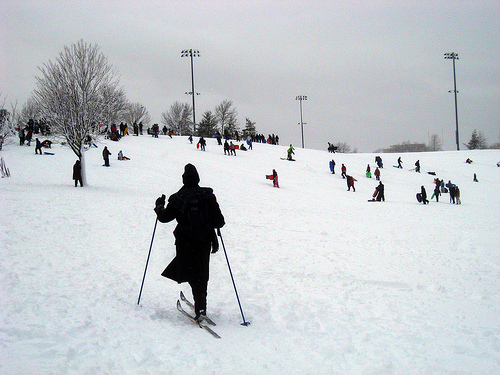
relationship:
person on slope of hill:
[135, 159, 258, 340] [13, 135, 497, 375]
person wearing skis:
[135, 159, 258, 340] [174, 289, 221, 342]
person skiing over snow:
[135, 159, 258, 340] [8, 127, 490, 374]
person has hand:
[135, 159, 258, 340] [153, 194, 169, 208]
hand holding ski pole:
[153, 194, 169, 208] [136, 194, 167, 306]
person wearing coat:
[135, 159, 258, 340] [154, 185, 226, 283]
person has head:
[135, 159, 258, 340] [181, 163, 204, 184]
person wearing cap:
[135, 159, 258, 340] [180, 164, 203, 184]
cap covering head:
[180, 164, 203, 184] [181, 163, 204, 184]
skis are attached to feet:
[174, 289, 221, 342] [196, 308, 210, 327]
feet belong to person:
[196, 308, 210, 327] [135, 159, 258, 340]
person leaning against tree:
[72, 160, 82, 189] [36, 36, 128, 186]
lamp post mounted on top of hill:
[179, 48, 204, 137] [13, 135, 497, 375]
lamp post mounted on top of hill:
[297, 93, 309, 151] [13, 135, 497, 375]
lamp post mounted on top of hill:
[444, 50, 462, 151] [13, 135, 497, 375]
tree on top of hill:
[163, 103, 196, 137] [13, 135, 497, 375]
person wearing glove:
[135, 159, 258, 340] [156, 197, 166, 208]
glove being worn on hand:
[156, 197, 166, 208] [153, 194, 169, 208]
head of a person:
[181, 163, 204, 184] [135, 159, 258, 340]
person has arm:
[135, 159, 258, 340] [155, 192, 177, 224]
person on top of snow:
[135, 159, 258, 340] [8, 127, 490, 374]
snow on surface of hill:
[8, 127, 490, 374] [13, 135, 497, 375]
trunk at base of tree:
[79, 155, 88, 187] [36, 36, 128, 186]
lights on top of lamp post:
[181, 49, 200, 59] [179, 48, 204, 137]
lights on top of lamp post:
[297, 94, 308, 102] [297, 93, 309, 151]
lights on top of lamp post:
[445, 50, 458, 61] [444, 50, 462, 151]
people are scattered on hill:
[105, 119, 479, 202] [13, 135, 497, 375]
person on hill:
[135, 159, 258, 340] [13, 135, 497, 375]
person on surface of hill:
[135, 159, 258, 340] [13, 135, 497, 375]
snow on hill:
[8, 127, 490, 374] [13, 135, 497, 375]